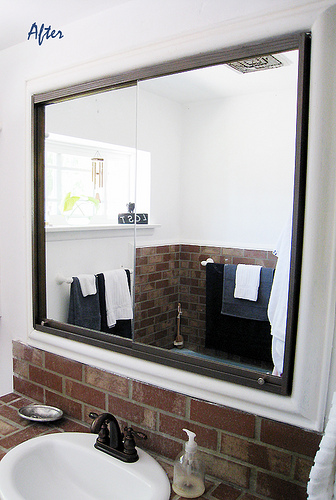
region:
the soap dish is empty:
[13, 385, 68, 426]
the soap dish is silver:
[1, 392, 68, 428]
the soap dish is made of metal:
[0, 381, 72, 430]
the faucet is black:
[61, 388, 166, 474]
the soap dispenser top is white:
[163, 422, 210, 457]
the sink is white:
[13, 435, 146, 493]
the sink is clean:
[7, 426, 144, 492]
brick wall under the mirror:
[55, 360, 241, 482]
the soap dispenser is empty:
[164, 420, 210, 496]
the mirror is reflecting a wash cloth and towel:
[139, 237, 270, 364]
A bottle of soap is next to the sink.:
[172, 428, 204, 497]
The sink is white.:
[18, 444, 86, 499]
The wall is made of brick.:
[223, 427, 300, 497]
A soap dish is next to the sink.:
[19, 404, 62, 421]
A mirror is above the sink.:
[29, 30, 311, 396]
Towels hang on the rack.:
[70, 272, 129, 322]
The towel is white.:
[108, 277, 125, 315]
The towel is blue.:
[226, 304, 263, 314]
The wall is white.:
[168, 81, 273, 226]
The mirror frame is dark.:
[34, 175, 44, 306]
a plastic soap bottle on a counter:
[160, 429, 234, 499]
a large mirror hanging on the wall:
[24, 74, 329, 351]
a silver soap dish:
[6, 392, 74, 432]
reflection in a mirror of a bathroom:
[26, 203, 280, 366]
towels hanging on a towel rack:
[59, 260, 152, 331]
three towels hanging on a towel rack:
[189, 246, 267, 362]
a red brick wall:
[59, 365, 98, 427]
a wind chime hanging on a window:
[85, 139, 112, 188]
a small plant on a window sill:
[61, 180, 99, 228]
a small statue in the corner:
[165, 291, 186, 355]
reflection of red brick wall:
[157, 275, 179, 305]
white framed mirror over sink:
[294, 422, 309, 430]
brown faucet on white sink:
[84, 407, 118, 461]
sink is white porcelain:
[76, 449, 94, 480]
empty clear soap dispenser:
[185, 474, 213, 479]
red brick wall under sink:
[234, 444, 256, 467]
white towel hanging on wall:
[313, 469, 319, 481]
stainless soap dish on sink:
[15, 404, 67, 435]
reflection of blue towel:
[99, 311, 115, 321]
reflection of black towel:
[121, 326, 131, 335]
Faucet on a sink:
[82, 400, 149, 467]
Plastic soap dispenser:
[166, 424, 215, 497]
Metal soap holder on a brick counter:
[16, 387, 71, 428]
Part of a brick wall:
[33, 357, 125, 411]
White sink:
[5, 412, 169, 496]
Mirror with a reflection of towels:
[40, 184, 132, 332]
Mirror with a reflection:
[22, 29, 312, 389]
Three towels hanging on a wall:
[195, 257, 274, 351]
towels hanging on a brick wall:
[196, 255, 266, 359]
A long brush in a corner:
[171, 293, 188, 347]